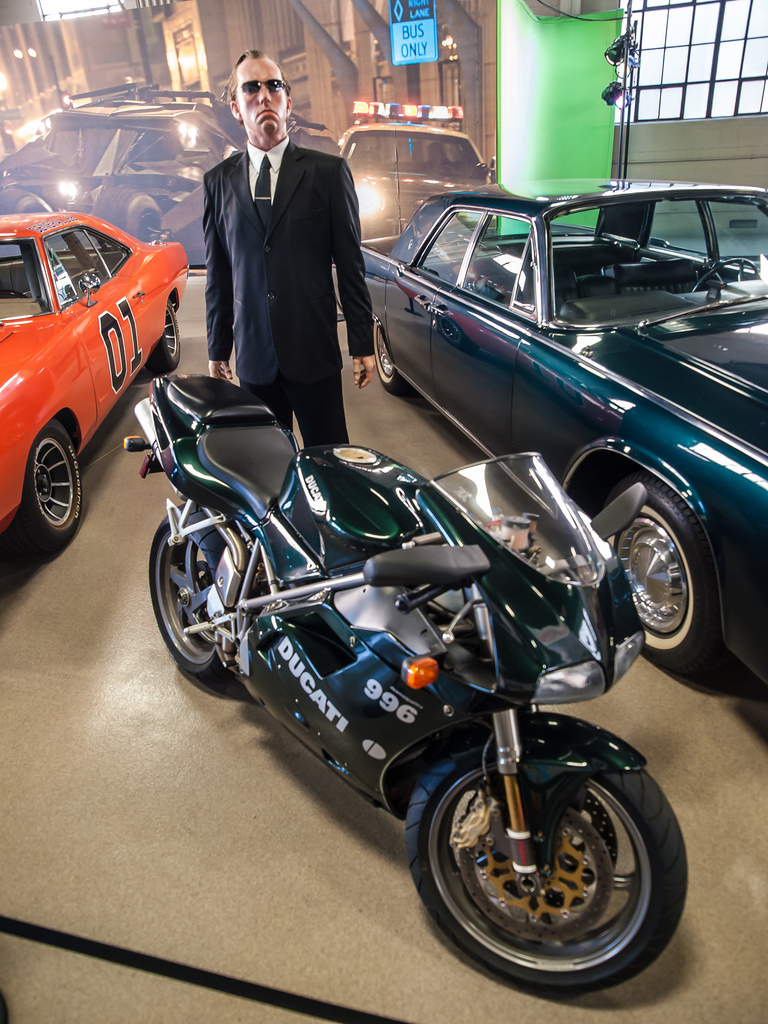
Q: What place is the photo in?
A: It is at the garage.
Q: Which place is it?
A: It is a garage.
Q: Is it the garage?
A: Yes, it is the garage.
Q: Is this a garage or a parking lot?
A: It is a garage.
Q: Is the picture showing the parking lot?
A: No, the picture is showing the garage.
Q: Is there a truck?
A: No, there are no trucks.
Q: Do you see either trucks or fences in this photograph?
A: No, there are no trucks or fences.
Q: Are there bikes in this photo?
A: Yes, there is a bike.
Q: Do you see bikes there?
A: Yes, there is a bike.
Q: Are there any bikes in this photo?
A: Yes, there is a bike.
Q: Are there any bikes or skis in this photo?
A: Yes, there is a bike.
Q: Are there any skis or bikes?
A: Yes, there is a bike.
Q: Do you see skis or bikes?
A: Yes, there is a bike.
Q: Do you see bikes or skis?
A: Yes, there is a bike.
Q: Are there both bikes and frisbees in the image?
A: No, there is a bike but no frisbees.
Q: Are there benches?
A: No, there are no benches.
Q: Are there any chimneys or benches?
A: No, there are no benches or chimneys.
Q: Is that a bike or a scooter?
A: That is a bike.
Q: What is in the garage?
A: The bike is in the garage.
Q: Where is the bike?
A: The bike is in the garage.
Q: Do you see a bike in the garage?
A: Yes, there is a bike in the garage.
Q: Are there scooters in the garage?
A: No, there is a bike in the garage.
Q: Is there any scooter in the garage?
A: No, there is a bike in the garage.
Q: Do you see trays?
A: No, there are no trays.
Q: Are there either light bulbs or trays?
A: No, there are no trays or light bulbs.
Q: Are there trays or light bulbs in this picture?
A: No, there are no trays or light bulbs.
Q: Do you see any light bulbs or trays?
A: No, there are no trays or light bulbs.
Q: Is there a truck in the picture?
A: No, there are no trucks.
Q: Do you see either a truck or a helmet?
A: No, there are no trucks or helmets.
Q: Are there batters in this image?
A: No, there are no batters.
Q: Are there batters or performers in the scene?
A: No, there are no batters or performers.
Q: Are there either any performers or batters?
A: No, there are no batters or performers.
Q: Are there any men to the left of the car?
A: Yes, there is a man to the left of the car.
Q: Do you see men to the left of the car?
A: Yes, there is a man to the left of the car.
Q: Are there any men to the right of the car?
A: No, the man is to the left of the car.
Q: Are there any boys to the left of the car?
A: No, there is a man to the left of the car.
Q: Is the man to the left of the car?
A: Yes, the man is to the left of the car.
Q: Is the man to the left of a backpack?
A: No, the man is to the left of the car.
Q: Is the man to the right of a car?
A: No, the man is to the left of a car.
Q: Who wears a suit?
A: The man wears a suit.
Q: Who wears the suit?
A: The man wears a suit.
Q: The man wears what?
A: The man wears a suit.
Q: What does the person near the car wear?
A: The man wears a suit.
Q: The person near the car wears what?
A: The man wears a suit.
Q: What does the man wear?
A: The man wears a suit.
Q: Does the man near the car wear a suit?
A: Yes, the man wears a suit.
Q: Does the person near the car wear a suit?
A: Yes, the man wears a suit.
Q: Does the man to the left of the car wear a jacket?
A: No, the man wears a suit.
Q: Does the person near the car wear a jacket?
A: No, the man wears a suit.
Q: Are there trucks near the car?
A: No, there is a man near the car.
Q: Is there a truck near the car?
A: No, there is a man near the car.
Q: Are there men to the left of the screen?
A: Yes, there is a man to the left of the screen.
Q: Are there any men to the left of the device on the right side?
A: Yes, there is a man to the left of the screen.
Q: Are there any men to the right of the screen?
A: No, the man is to the left of the screen.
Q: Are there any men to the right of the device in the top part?
A: No, the man is to the left of the screen.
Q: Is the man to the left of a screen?
A: Yes, the man is to the left of a screen.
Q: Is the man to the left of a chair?
A: No, the man is to the left of a screen.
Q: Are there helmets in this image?
A: No, there are no helmets.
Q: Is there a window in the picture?
A: Yes, there are windows.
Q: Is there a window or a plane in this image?
A: Yes, there are windows.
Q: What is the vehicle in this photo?
A: The vehicle is a car.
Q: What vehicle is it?
A: The vehicle is a car.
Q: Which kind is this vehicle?
A: That is a car.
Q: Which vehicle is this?
A: That is a car.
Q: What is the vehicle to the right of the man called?
A: The vehicle is a car.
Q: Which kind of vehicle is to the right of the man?
A: The vehicle is a car.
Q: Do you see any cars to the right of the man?
A: Yes, there is a car to the right of the man.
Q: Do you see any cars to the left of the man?
A: No, the car is to the right of the man.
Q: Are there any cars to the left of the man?
A: No, the car is to the right of the man.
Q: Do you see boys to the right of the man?
A: No, there is a car to the right of the man.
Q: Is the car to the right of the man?
A: Yes, the car is to the right of the man.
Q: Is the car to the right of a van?
A: No, the car is to the right of the man.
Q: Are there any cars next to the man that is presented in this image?
A: Yes, there is a car next to the man.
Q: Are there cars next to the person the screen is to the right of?
A: Yes, there is a car next to the man.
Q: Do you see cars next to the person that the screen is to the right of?
A: Yes, there is a car next to the man.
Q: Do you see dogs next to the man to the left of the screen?
A: No, there is a car next to the man.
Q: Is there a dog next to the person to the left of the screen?
A: No, there is a car next to the man.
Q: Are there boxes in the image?
A: No, there are no boxes.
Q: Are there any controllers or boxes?
A: No, there are no boxes or controllers.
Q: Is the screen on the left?
A: No, the screen is on the right of the image.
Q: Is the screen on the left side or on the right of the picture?
A: The screen is on the right of the image.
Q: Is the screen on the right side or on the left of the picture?
A: The screen is on the right of the image.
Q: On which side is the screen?
A: The screen is on the right of the image.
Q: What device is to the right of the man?
A: The device is a screen.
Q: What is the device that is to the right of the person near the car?
A: The device is a screen.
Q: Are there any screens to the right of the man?
A: Yes, there is a screen to the right of the man.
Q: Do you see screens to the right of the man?
A: Yes, there is a screen to the right of the man.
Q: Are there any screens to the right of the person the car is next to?
A: Yes, there is a screen to the right of the man.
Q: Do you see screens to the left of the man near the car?
A: No, the screen is to the right of the man.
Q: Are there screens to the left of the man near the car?
A: No, the screen is to the right of the man.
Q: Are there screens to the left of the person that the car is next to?
A: No, the screen is to the right of the man.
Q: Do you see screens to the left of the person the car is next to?
A: No, the screen is to the right of the man.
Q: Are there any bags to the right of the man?
A: No, there is a screen to the right of the man.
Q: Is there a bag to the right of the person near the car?
A: No, there is a screen to the right of the man.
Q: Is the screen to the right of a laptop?
A: No, the screen is to the right of the man.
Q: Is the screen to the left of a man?
A: No, the screen is to the right of a man.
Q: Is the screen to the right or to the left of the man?
A: The screen is to the right of the man.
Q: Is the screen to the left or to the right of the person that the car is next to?
A: The screen is to the right of the man.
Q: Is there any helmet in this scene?
A: No, there are no helmets.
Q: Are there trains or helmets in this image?
A: No, there are no helmets or trains.